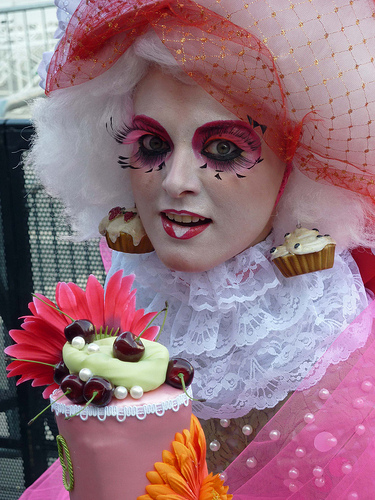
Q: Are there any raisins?
A: No, there are no raisins.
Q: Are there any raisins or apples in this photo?
A: No, there are no raisins or apples.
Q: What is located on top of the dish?
A: The cherry is on top of the dish.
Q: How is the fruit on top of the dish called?
A: The fruit is a cherry.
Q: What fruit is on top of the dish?
A: The fruit is a cherry.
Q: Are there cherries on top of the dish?
A: Yes, there is a cherry on top of the dish.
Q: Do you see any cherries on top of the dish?
A: Yes, there is a cherry on top of the dish.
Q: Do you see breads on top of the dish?
A: No, there is a cherry on top of the dish.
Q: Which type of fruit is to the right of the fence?
A: The fruit is a cherry.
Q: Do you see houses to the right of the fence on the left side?
A: No, there is a cherry to the right of the fence.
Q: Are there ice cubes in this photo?
A: No, there are no ice cubes.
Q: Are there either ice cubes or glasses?
A: No, there are no ice cubes or glasses.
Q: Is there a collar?
A: Yes, there is a collar.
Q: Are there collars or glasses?
A: Yes, there is a collar.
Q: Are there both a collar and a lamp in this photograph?
A: No, there is a collar but no lamps.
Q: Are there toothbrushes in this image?
A: No, there are no toothbrushes.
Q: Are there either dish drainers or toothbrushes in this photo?
A: No, there are no toothbrushes or dish drainers.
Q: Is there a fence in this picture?
A: Yes, there is a fence.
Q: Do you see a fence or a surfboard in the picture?
A: Yes, there is a fence.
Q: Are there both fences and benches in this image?
A: No, there is a fence but no benches.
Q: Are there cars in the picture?
A: No, there are no cars.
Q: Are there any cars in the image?
A: No, there are no cars.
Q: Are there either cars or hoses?
A: No, there are no cars or hoses.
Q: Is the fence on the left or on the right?
A: The fence is on the left of the image.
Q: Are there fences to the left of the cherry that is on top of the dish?
A: Yes, there is a fence to the left of the cherry.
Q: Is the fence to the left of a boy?
A: No, the fence is to the left of a cherry.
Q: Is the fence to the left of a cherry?
A: Yes, the fence is to the left of a cherry.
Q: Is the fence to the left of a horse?
A: No, the fence is to the left of a cherry.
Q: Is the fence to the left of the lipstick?
A: Yes, the fence is to the left of the lipstick.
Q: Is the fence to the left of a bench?
A: No, the fence is to the left of the lipstick.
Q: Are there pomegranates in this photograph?
A: No, there are no pomegranates.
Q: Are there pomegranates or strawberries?
A: No, there are no pomegranates or strawberries.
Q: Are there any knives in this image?
A: No, there are no knives.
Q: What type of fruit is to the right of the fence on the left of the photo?
A: The fruit is a cherry.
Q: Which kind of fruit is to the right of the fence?
A: The fruit is a cherry.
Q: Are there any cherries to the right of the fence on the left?
A: Yes, there is a cherry to the right of the fence.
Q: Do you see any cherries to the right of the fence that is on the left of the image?
A: Yes, there is a cherry to the right of the fence.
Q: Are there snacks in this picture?
A: No, there are no snacks.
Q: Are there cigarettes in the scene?
A: No, there are no cigarettes.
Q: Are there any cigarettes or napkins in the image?
A: No, there are no cigarettes or napkins.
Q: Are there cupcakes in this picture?
A: Yes, there is a cupcake.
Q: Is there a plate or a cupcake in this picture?
A: Yes, there is a cupcake.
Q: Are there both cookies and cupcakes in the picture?
A: No, there is a cupcake but no cookies.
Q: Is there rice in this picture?
A: No, there is no rice.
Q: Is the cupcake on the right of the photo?
A: Yes, the cupcake is on the right of the image.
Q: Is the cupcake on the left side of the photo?
A: No, the cupcake is on the right of the image.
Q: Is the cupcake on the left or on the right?
A: The cupcake is on the right of the image.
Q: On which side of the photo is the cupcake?
A: The cupcake is on the right of the image.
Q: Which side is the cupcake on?
A: The cupcake is on the right of the image.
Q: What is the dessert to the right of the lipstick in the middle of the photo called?
A: The dessert is a cupcake.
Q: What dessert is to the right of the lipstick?
A: The dessert is a cupcake.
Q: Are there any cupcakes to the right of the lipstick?
A: Yes, there is a cupcake to the right of the lipstick.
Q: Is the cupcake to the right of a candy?
A: No, the cupcake is to the right of the lipstick.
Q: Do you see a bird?
A: No, there are no birds.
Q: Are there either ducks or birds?
A: No, there are no birds or ducks.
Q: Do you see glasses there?
A: No, there are no glasses.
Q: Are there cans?
A: No, there are no cans.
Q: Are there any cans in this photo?
A: No, there are no cans.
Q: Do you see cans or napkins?
A: No, there are no cans or napkins.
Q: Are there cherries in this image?
A: Yes, there are cherries.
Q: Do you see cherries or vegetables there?
A: Yes, there are cherries.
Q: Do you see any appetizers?
A: No, there are no appetizers.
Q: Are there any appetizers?
A: No, there are no appetizers.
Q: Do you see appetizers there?
A: No, there are no appetizers.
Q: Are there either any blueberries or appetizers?
A: No, there are no appetizers or blueberries.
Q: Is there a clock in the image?
A: No, there are no clocks.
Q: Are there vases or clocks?
A: No, there are no clocks or vases.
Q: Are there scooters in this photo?
A: No, there are no scooters.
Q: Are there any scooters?
A: No, there are no scooters.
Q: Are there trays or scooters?
A: No, there are no scooters or trays.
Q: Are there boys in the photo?
A: No, there are no boys.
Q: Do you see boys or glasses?
A: No, there are no boys or glasses.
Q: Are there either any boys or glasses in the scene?
A: No, there are no boys or glasses.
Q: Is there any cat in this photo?
A: No, there are no cats.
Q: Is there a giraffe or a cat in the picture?
A: No, there are no cats or giraffes.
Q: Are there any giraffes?
A: No, there are no giraffes.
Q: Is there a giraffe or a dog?
A: No, there are no giraffes or dogs.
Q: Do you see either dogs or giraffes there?
A: No, there are no giraffes or dogs.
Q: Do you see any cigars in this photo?
A: No, there are no cigars.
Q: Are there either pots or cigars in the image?
A: No, there are no cigars or pots.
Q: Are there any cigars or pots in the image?
A: No, there are no cigars or pots.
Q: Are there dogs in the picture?
A: No, there are no dogs.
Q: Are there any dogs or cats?
A: No, there are no dogs or cats.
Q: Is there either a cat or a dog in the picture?
A: No, there are no dogs or cats.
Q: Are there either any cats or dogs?
A: No, there are no dogs or cats.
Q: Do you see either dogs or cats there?
A: No, there are no dogs or cats.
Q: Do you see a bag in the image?
A: No, there are no bags.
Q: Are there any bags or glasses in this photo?
A: No, there are no bags or glasses.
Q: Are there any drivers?
A: No, there are no drivers.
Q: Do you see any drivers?
A: No, there are no drivers.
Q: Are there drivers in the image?
A: No, there are no drivers.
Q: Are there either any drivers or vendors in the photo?
A: No, there are no drivers or vendors.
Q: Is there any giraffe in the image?
A: No, there are no giraffes.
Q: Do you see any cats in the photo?
A: No, there are no cats.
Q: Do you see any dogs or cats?
A: No, there are no cats or dogs.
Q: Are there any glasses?
A: No, there are no glasses.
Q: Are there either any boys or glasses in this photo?
A: No, there are no glasses or boys.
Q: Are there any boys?
A: No, there are no boys.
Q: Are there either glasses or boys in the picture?
A: No, there are no boys or glasses.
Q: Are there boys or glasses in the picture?
A: No, there are no boys or glasses.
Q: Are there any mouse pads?
A: No, there are no mouse pads.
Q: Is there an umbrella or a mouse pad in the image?
A: No, there are no mouse pads or umbrellas.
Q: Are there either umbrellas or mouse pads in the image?
A: No, there are no mouse pads or umbrellas.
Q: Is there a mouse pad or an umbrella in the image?
A: No, there are no mouse pads or umbrellas.